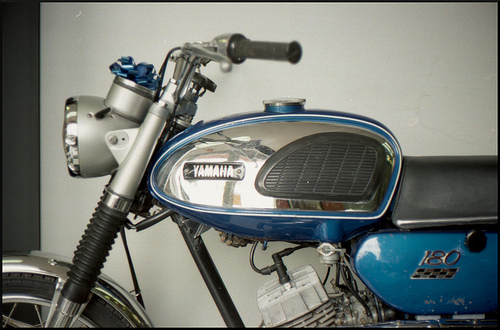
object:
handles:
[212, 34, 306, 70]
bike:
[0, 31, 500, 330]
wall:
[41, 0, 500, 330]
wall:
[0, 0, 40, 330]